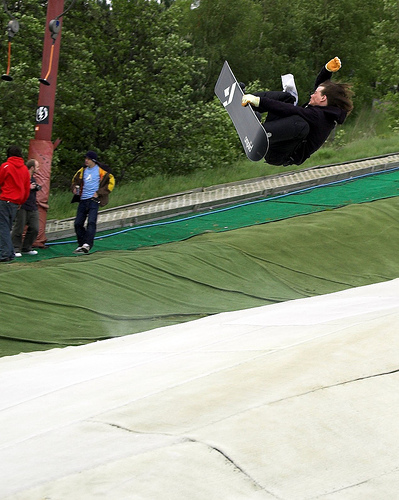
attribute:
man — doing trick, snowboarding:
[244, 46, 354, 173]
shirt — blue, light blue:
[78, 168, 102, 203]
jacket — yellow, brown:
[66, 164, 119, 208]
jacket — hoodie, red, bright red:
[2, 156, 33, 207]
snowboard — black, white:
[209, 62, 274, 167]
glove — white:
[240, 91, 260, 111]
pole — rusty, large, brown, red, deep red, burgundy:
[26, 6, 69, 248]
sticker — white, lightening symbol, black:
[31, 103, 52, 126]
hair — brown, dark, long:
[321, 79, 351, 113]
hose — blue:
[33, 175, 398, 245]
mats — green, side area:
[16, 163, 398, 246]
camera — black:
[36, 181, 47, 195]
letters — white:
[243, 137, 258, 158]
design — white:
[217, 81, 242, 111]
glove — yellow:
[321, 55, 344, 76]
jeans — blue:
[71, 198, 101, 253]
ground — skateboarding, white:
[3, 287, 392, 499]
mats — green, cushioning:
[2, 195, 398, 345]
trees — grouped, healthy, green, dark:
[3, 3, 398, 185]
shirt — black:
[262, 92, 342, 160]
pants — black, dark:
[259, 113, 308, 167]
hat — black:
[84, 151, 96, 163]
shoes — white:
[15, 249, 42, 259]